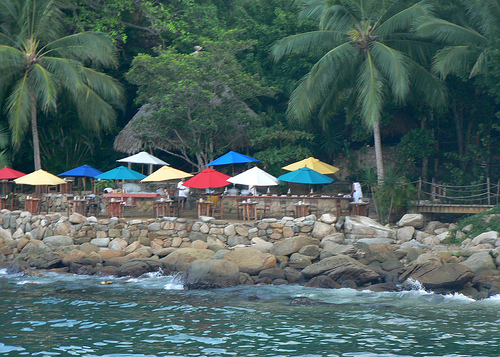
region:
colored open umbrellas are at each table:
[1, 140, 372, 220]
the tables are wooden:
[21, 188, 313, 224]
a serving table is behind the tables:
[217, 180, 349, 220]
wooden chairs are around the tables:
[170, 195, 350, 228]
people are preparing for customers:
[99, 180, 371, 210]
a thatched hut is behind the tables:
[113, 87, 268, 221]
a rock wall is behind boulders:
[1, 207, 403, 274]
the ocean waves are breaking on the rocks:
[13, 237, 496, 353]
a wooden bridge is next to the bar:
[393, 170, 492, 229]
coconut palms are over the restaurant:
[6, 6, 496, 245]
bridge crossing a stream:
[395, 173, 497, 226]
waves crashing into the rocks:
[119, 264, 205, 301]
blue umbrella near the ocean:
[279, 165, 331, 208]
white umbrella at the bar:
[226, 164, 274, 221]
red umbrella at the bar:
[184, 165, 225, 226]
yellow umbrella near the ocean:
[138, 163, 188, 218]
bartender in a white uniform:
[346, 174, 367, 214]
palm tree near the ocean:
[310, 28, 424, 219]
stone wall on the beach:
[5, 210, 319, 250]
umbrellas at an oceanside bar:
[16, 143, 370, 225]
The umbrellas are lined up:
[1, 130, 348, 213]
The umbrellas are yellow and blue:
[274, 155, 343, 195]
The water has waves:
[69, 290, 251, 355]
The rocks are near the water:
[116, 213, 484, 303]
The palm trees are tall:
[1, 29, 125, 194]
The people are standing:
[128, 160, 308, 251]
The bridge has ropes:
[369, 88, 498, 253]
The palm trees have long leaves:
[304, 28, 412, 137]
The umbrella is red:
[172, 156, 236, 198]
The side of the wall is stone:
[66, 192, 404, 259]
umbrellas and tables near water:
[27, 166, 307, 303]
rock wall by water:
[43, 191, 258, 307]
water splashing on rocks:
[47, 233, 254, 323]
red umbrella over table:
[180, 165, 235, 205]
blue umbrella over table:
[63, 162, 113, 207]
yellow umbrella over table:
[134, 161, 208, 224]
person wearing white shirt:
[168, 167, 203, 211]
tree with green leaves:
[133, 44, 265, 198]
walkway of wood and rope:
[382, 156, 497, 249]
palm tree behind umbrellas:
[281, 21, 446, 226]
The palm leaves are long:
[293, 15, 425, 145]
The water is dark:
[71, 290, 211, 352]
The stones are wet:
[169, 242, 261, 319]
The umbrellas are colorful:
[61, 125, 338, 188]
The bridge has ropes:
[392, 150, 493, 215]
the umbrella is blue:
[194, 132, 271, 176]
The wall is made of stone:
[69, 220, 299, 290]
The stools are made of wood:
[155, 187, 400, 242]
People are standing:
[107, 136, 255, 258]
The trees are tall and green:
[125, 50, 367, 207]